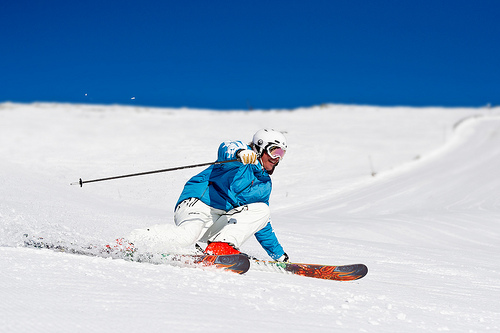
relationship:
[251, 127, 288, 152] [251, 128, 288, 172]
helmet worn on head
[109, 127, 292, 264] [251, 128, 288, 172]
person has head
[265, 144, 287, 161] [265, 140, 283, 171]
goggles worn on face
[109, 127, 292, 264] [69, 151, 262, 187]
person holding ski pole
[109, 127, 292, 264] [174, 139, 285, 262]
person wearing jacket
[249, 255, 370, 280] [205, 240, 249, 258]
ski worn on foot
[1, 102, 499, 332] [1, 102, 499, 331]
ground covered in snow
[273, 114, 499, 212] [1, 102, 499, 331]
mark in middle of snow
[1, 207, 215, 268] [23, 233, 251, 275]
snow kicked up from ski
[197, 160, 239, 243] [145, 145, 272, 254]
shadow on front of body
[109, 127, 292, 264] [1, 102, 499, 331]
person skiing in snow